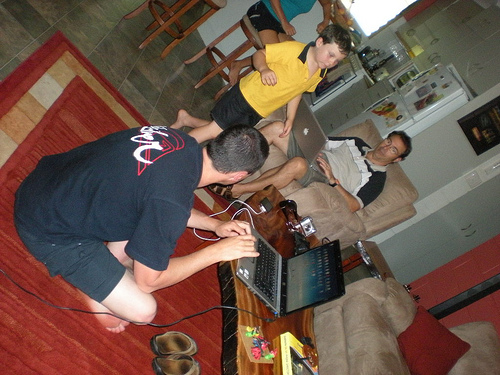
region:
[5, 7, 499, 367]
interior of kichen and living room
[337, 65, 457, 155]
front of white refrigerator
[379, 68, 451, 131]
magnets on white appliance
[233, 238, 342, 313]
open laptop on table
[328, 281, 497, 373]
red pillow on couch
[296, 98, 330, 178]
open computer on lap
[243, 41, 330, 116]
black collar on yellow shirt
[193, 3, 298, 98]
person on wood stool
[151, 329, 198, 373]
pair of slippers on floor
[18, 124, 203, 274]
design on black shirt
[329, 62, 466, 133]
a white refrigerator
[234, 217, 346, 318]
a laptop computer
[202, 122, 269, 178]
a man's short cut black hair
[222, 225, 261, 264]
the hand of a man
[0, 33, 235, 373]
part of a large red rug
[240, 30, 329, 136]
a boy's yellow and black shirt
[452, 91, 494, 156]
part of a picture frame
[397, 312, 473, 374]
a red pillow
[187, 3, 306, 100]
part of a wooden chair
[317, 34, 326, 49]
the ear of a boy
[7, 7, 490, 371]
a very dizzy angle of a suburban family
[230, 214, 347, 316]
a laptop on the coffee table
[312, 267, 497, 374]
the sofa is light brown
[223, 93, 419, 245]
dad sitting in a lounge chair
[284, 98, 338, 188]
dad has a laptop open on his lap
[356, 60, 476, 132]
lots of stuff hanging on the fridge doors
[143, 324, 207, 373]
a pair of shoes under the coffee table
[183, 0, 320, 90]
mom sitting on a bar stool at the breakfast bar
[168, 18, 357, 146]
younger son approaching the coffee table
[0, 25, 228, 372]
big red rug spread out on the living room floor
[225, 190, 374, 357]
a laptop on the table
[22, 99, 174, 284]
the shirt is black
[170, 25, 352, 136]
boy in yellow and black shirt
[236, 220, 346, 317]
open laptop computer on table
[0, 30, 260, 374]
red tan and white carpet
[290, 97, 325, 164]
silver apple macbook laptop computer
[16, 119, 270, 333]
guy in black shirt sitting on floor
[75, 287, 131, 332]
barefoot foot on red rug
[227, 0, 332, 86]
woman wearing blue and black outfit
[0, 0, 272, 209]
multi-colored grey tiles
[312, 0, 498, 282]
white cabinets in kitchen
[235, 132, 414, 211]
man in tan white and black shirt